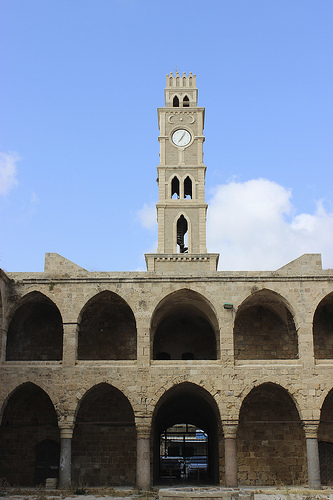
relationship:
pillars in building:
[55, 318, 328, 484] [114, 42, 293, 394]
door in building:
[28, 436, 61, 489] [7, 253, 332, 498]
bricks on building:
[0, 69, 332, 497] [102, 35, 260, 375]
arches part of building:
[158, 169, 200, 199] [148, 60, 224, 296]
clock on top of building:
[165, 123, 198, 151] [3, 61, 324, 494]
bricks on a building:
[238, 313, 295, 358] [3, 61, 324, 494]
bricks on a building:
[99, 271, 178, 365] [3, 61, 324, 494]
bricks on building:
[222, 290, 237, 300] [3, 61, 324, 494]